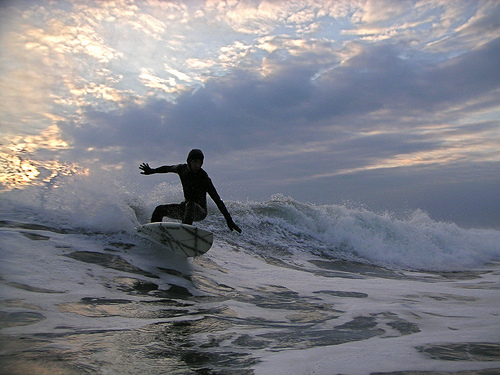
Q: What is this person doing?
A: Surfing.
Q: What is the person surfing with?
A: Surfboard.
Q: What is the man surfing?
A: Wave.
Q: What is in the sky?
A: Clouds.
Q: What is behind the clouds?
A: The sun.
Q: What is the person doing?
A: Surfing.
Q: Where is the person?
A: In the ocean.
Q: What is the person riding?
A: A surfboard.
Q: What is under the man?
A: A surfboard.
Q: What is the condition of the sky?
A: Cloudy.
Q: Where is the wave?
A: Behind the man.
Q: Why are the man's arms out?
A: For balance.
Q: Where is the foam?
A: In the water.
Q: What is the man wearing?
A: A wetsuit.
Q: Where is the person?
A: Ocean.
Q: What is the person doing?
A: Surfing.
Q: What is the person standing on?
A: Surfboard.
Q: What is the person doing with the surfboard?
A: Riding ocean wave.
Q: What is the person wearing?
A: Wetsuit.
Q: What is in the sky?
A: Clouds.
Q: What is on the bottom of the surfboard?
A: Criss cross stripes.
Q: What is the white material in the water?
A: Froth and waves.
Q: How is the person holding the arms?
A: Out in front of them on either sides.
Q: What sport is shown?
A: Surfing.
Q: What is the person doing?
A: Surfing.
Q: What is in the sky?
A: Clouds.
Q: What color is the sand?
A: No sand.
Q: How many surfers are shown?
A: One.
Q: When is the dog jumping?
A: There is no dog.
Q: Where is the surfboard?
A: In the water.